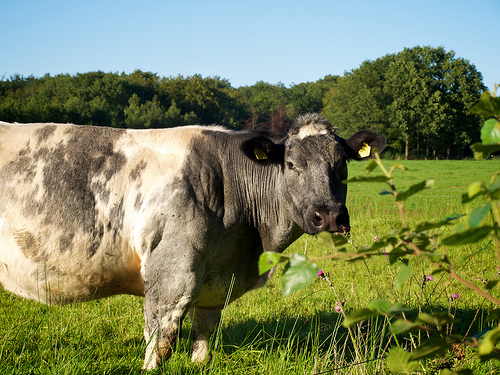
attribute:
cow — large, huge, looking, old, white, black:
[2, 110, 349, 374]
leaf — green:
[441, 218, 494, 253]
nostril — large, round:
[310, 212, 326, 226]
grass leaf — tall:
[208, 271, 247, 367]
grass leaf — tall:
[271, 308, 282, 367]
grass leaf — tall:
[41, 281, 73, 373]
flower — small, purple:
[316, 268, 325, 279]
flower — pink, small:
[424, 271, 435, 284]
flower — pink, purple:
[449, 288, 464, 307]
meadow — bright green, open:
[0, 156, 497, 374]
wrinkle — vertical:
[250, 162, 259, 229]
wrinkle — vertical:
[255, 168, 271, 249]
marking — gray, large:
[44, 124, 109, 249]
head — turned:
[242, 116, 378, 235]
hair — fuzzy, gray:
[290, 112, 331, 127]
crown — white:
[296, 122, 330, 140]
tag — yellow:
[254, 146, 268, 161]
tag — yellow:
[358, 142, 371, 161]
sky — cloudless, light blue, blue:
[3, 3, 497, 88]